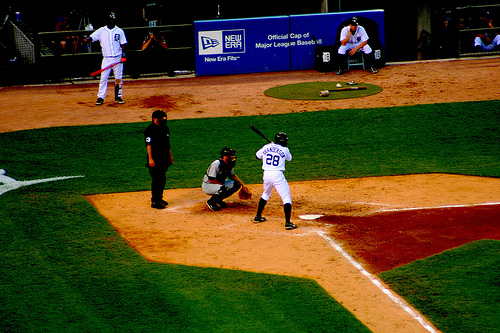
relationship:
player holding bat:
[255, 130, 298, 232] [248, 123, 271, 144]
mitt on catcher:
[238, 185, 254, 199] [201, 144, 248, 212]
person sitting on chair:
[335, 13, 378, 74] [346, 61, 364, 70]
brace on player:
[113, 84, 123, 100] [80, 9, 129, 106]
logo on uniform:
[113, 34, 121, 43] [90, 25, 130, 100]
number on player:
[266, 154, 280, 166] [255, 130, 298, 232]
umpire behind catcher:
[144, 107, 172, 210] [201, 144, 248, 212]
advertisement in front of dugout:
[194, 13, 335, 76] [33, 1, 498, 84]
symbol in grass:
[0, 166, 87, 196] [0, 195, 365, 333]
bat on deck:
[326, 87, 369, 93] [264, 80, 383, 99]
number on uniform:
[266, 154, 280, 166] [256, 143, 292, 206]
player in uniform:
[255, 130, 298, 232] [256, 143, 292, 206]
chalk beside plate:
[315, 226, 438, 332] [298, 212, 325, 222]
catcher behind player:
[201, 144, 248, 212] [255, 130, 298, 232]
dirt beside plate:
[317, 204, 500, 263] [298, 212, 325, 222]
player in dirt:
[255, 130, 298, 232] [317, 204, 500, 263]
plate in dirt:
[298, 212, 325, 222] [317, 204, 500, 263]